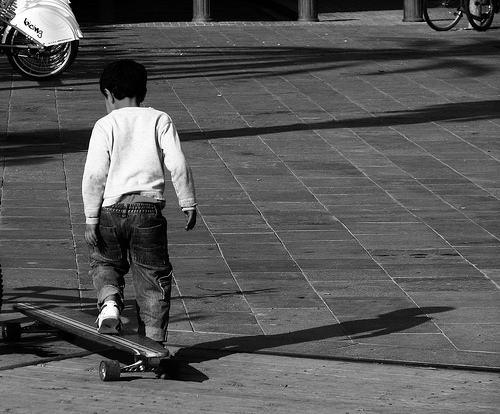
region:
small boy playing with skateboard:
[11, 55, 194, 387]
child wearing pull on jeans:
[86, 200, 174, 327]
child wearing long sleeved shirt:
[79, 107, 196, 227]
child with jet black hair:
[99, 52, 153, 104]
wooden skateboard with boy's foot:
[1, 291, 166, 397]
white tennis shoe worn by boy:
[94, 304, 124, 344]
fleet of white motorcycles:
[9, 0, 84, 77]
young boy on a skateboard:
[6, 52, 195, 388]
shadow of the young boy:
[175, 296, 456, 384]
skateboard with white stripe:
[11, 294, 163, 382]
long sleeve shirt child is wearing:
[82, 111, 189, 211]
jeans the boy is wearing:
[88, 202, 168, 321]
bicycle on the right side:
[421, 4, 492, 36]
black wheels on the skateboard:
[5, 319, 177, 381]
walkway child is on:
[5, 24, 498, 371]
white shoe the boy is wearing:
[93, 302, 121, 336]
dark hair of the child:
[93, 55, 147, 100]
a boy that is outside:
[44, 68, 253, 336]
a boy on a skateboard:
[74, 94, 211, 409]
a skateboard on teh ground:
[32, 284, 216, 402]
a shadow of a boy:
[161, 284, 497, 401]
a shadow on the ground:
[180, 215, 450, 366]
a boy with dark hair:
[23, 45, 230, 227]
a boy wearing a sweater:
[73, 79, 229, 266]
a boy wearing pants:
[72, 67, 207, 355]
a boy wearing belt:
[52, 81, 229, 386]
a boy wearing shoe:
[85, 265, 158, 376]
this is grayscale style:
[76, 45, 378, 350]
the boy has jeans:
[67, 162, 187, 317]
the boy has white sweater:
[85, 113, 206, 214]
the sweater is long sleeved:
[75, 115, 246, 227]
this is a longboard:
[65, 263, 246, 405]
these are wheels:
[68, 333, 169, 403]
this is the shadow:
[237, 280, 484, 386]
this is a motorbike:
[14, 21, 81, 100]